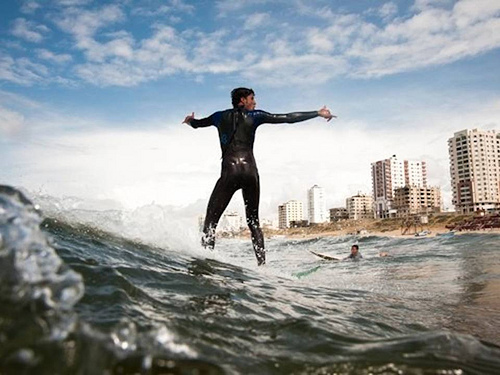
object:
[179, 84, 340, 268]
man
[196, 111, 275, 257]
wet suit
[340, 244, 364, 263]
man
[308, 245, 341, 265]
surfboard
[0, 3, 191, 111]
sky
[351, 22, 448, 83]
clouds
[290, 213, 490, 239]
beach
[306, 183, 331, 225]
hotels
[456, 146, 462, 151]
windows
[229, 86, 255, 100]
hair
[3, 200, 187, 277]
wave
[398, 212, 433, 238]
lifeguard stand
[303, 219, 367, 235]
dunes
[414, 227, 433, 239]
boats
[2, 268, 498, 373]
ocean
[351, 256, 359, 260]
belly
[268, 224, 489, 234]
shore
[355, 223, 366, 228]
soil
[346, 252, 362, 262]
shirt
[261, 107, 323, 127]
arms